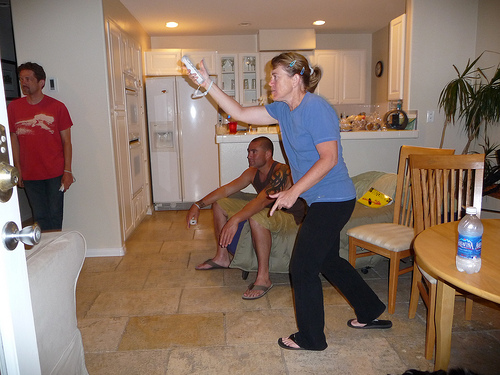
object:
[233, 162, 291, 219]
arm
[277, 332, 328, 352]
shoes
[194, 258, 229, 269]
shoes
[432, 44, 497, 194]
plants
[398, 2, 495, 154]
wall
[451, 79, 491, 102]
green leaves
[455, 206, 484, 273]
bottle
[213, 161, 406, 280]
armchair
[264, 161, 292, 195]
tatoo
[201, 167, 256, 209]
arm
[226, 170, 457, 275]
couch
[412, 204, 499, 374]
table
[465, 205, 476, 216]
white top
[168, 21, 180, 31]
lights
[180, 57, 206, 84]
control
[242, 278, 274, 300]
flip flops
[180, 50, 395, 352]
people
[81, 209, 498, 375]
floor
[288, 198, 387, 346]
pants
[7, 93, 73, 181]
red shirt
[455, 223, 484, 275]
water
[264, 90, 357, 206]
shirt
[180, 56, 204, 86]
woman's hand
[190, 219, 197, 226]
remote control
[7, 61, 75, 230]
guy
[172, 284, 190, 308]
lines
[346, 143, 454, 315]
chair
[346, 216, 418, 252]
seat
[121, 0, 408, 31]
ceiling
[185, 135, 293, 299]
guy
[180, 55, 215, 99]
game